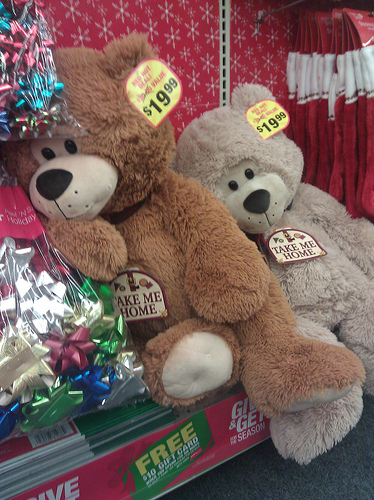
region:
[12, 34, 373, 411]
Two brown teddy bears on sale at a store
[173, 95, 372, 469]
a beige teddy bear for sale with a price tag in his ear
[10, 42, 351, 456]
a brown teddy bear for sale in a store with a price tag in his ear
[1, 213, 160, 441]
a plastic bag filled with bows for gift wrapping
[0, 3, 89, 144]
the corner of a plastic bag filled with bows for gift wrapping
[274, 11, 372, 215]
many red and white Christmas stockings hanging on a hook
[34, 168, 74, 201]
a big brown nose on the teddy bear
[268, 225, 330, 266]
a tag hanging on the teddy bear that says "Take me home"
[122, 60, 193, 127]
a yellow and red price tag on the teddy bear with a price of $19.99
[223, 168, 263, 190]
two brown eyes on the teddy bear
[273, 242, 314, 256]
TAKE ME HOME hangtag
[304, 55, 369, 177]
red and white Christmas stockings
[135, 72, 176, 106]
$19.99 pricetag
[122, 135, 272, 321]
two stuffed toy bears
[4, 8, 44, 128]
Christmas gift bows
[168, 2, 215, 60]
red and white snowflake pattern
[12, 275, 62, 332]
silver gift bow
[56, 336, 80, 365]
red gift bow in a clear bag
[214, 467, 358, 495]
dark gray carpeted floor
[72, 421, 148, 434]
Christmas tissue paper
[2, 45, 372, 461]
Two teddy bears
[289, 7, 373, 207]
A bunch of Christmas stockings hanging on a hook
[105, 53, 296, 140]
Two $19.99 price tags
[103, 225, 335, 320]
Two take me home tags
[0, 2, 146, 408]
Two bags of Christmas bows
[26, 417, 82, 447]
A bar code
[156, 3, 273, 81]
Red background with white snowflakes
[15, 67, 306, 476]
A brown teddy bear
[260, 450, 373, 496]
Dark blue carpet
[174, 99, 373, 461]
A tan teddy bear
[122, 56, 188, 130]
a yellow price tag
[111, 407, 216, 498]
a green sticker on the box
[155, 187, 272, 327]
the arm of a teddy bear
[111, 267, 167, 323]
a tan and red tag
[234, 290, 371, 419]
the leg of a teddy bear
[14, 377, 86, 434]
a shiny green bow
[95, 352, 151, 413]
a shiny silver bow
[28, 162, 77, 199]
the nose of a teddy bear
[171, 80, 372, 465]
a fluffy gray teddy bear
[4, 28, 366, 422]
a fluffy brown teddy bear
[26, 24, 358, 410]
grey and brown stuffed animals for sale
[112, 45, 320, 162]
tags on the bears' ears showing the price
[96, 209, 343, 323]
signs at the toys' necks telling customers what to do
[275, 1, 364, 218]
stack of red and white holiday decorations on wall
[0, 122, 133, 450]
bear leaning on packages of bows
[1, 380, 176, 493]
folded tissue paper in plastic bags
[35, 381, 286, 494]
sign on bottom of ledge with store offer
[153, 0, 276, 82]
pattern of white snowflakes on red background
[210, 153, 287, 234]
small black eyes and large black nose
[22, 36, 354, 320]
one bear leaning on the other bear